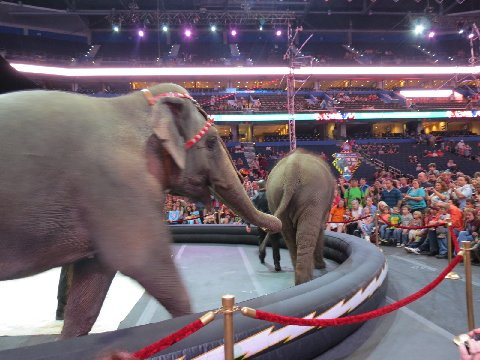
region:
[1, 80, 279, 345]
The elephant is gray.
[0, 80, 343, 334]
Elephant is holding tail.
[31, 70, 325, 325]
Tail in elephant's trunk.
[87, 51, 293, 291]
Elephant has floppy ear.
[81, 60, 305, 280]
Harness on elephant's head.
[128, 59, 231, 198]
Harness is red and white.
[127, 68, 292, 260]
The elephant has an eye.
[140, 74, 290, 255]
Elephant's eye is open.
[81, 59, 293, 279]
Elephant's mouth is open.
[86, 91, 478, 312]
People watching the elephants,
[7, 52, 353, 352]
elephants walking in circle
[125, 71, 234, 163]
red strap on elephant's head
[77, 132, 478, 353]
red ropes around elephants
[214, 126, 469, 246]
people watching the elephants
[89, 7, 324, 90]
multi colored lights on ceiling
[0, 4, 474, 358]
elephants are in a stadium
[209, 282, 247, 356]
the pole is gold colored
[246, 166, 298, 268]
man walking beside elephant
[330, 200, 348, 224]
person's shirt is orange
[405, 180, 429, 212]
woman's shirt is blue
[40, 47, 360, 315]
elephant holding another elephants tail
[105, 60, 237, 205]
elephant wearing a red bridle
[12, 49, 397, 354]
two elephants walking in a circle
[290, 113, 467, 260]
crowd of people watching a show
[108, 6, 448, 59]
bright stage lights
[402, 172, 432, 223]
woman wearing an aqua shirt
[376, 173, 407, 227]
man wearing a blue shirt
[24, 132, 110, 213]
rough grey elephant hide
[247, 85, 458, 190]
two levels of bleachers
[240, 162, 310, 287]
man leading an elephant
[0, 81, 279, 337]
a large grey elephant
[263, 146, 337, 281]
a large grey elephant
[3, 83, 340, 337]
an elephant holding another elephant's tail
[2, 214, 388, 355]
an inflatable circus ring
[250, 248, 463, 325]
a red velvet rope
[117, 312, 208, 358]
a red velvet rope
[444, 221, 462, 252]
a red velvet rope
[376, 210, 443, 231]
a red velvet rope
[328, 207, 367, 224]
a red velvet rope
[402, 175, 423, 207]
a woman standing and applauding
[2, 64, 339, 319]
Elephants walking around ring at circus.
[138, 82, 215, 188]
Red headdress on elephant.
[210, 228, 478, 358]
Red cloth rail aroung ring at circus.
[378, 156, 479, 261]
People sitting and standing in bleachers.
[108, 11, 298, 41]
Lights mounted at top of ceiling.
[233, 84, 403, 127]
Bleachers at top row seats.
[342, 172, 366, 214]
Man standing in audience wearing green shirt.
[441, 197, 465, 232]
Person in bleachers dressed in orange shirt.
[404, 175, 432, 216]
Woman standing in audience wearing turqoise top.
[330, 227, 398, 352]
Edge of gray ring in circus.